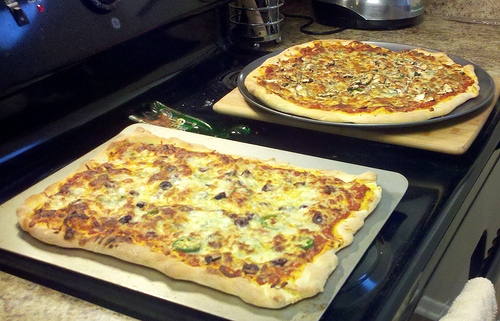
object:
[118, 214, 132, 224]
olives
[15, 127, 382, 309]
orange cheese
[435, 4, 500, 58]
counter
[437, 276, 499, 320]
towel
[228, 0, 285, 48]
holder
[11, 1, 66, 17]
circle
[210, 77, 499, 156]
board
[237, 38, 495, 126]
pizza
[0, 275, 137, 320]
counter top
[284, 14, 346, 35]
cord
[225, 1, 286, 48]
utensil holder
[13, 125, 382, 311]
rectangle crust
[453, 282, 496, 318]
white towel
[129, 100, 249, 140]
spoon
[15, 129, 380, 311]
rectangle pizza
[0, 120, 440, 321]
baking sheet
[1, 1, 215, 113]
black stove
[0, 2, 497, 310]
appliance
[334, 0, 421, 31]
kettle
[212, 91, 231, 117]
edge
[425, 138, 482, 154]
edge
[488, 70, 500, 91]
edge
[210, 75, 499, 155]
cutting board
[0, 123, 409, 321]
dish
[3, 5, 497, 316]
stove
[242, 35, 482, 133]
soda cans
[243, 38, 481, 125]
pizza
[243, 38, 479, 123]
crust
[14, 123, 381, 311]
pizza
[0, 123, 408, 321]
sheet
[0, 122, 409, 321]
trays